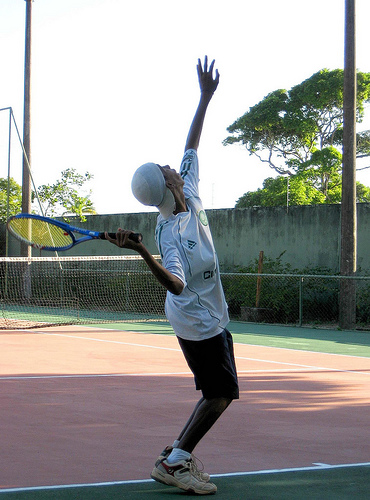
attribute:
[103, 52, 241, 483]
man — playing tennis, caucasian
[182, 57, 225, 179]
arm — extended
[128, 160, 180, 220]
hat — white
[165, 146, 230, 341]
shirt — white, black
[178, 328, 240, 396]
shorts — black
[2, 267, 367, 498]
tennis court — red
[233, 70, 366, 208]
tree — tall, green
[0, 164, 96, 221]
tree — green, tall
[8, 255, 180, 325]
net — white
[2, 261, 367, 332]
fence — chainlink, metal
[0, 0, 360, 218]
sky — white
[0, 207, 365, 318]
wall — concrete, stoned, grey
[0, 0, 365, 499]
scene — durind day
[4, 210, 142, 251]
tennis racket — blue, yellow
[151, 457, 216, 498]
sneakers — grey, red, black, tan, white, brown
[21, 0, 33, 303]
pole — wooden, brown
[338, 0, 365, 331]
pole — wooden, brown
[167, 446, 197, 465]
sock — bright, white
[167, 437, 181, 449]
sock — bright, white